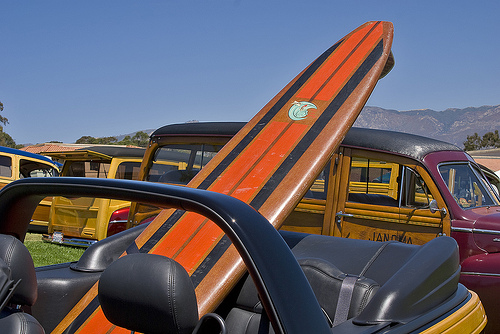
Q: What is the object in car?
A: Surfboard.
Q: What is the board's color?
A: Orange and black.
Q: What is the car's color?
A: Yellow.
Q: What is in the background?
A: Mountainside.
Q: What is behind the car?
A: Old truck.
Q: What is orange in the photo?
A: Surfboard.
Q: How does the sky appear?
A: Clear and blue/.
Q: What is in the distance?
A: Mountains.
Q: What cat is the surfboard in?
A: Jeep.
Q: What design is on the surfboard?
A: Striped.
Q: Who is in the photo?
A: No one.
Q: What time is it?
A: Daytime.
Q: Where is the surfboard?
A: In the car.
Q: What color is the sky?
A: Blue.